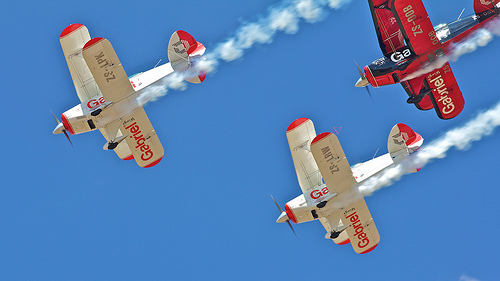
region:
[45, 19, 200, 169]
red and white plane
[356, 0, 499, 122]
black and red plane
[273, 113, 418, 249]
plane flying in air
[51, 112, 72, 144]
propeller on air plane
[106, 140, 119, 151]
black tire on plane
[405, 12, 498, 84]
entrail from flying plane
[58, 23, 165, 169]
wings on air plane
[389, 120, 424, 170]
tail on air plane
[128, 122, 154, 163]
red writing on plane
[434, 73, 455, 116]
white writing on plane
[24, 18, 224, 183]
Red and white jet with smoke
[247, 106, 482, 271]
Red and white jet with smoke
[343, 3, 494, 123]
Red and black jet with smoke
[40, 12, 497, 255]
Three jets in the sky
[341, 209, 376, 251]
red letters written on the plane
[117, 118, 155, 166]
red letters written on the plane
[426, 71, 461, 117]
White letters written on the plane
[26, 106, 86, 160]
Propeller on the jet plane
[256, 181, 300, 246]
Propeller on the jet plane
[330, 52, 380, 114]
Propeller on the jet plane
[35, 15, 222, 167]
A red and white airplane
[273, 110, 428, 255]
A red and white airplane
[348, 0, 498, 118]
A red and black airplane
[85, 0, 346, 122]
some white smoke coming from an airplane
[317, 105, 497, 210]
some white smoke coming from an airplane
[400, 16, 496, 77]
some white smoke coming from an airplane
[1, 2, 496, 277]
A clear, blue sky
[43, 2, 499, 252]
A trio of airplanes doing a stunt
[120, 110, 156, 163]
branding on the red and white airplane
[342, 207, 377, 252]
branding on the red and white airplane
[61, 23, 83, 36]
wing tip is red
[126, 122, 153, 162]
red writing under white wing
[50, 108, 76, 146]
propeller on plane is spinning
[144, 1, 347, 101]
exhaust behind plane is white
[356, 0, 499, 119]
red plane against blue sky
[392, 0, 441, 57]
wing is red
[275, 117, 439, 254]
plane in front of plane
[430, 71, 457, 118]
white writing on a red wing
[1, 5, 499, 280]
blue sky behind white plane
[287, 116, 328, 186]
wing above wing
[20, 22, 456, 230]
three airplanes in formation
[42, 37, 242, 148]
red and white airplane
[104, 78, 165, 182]
red writing on bottom of airplane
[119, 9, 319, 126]
white contrails from plane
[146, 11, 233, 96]
red and white tail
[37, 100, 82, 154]
white propeller on plane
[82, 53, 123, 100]
black letters on underside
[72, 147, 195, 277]
sky is blue and clear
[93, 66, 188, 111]
white body of plane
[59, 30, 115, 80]
red tips of wings